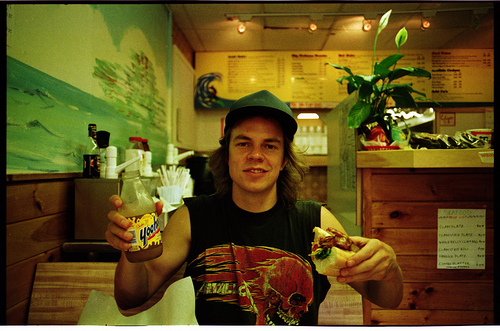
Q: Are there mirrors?
A: No, there are no mirrors.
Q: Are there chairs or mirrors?
A: No, there are no mirrors or chairs.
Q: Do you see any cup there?
A: Yes, there is a cup.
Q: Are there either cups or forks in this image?
A: Yes, there is a cup.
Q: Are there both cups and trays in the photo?
A: No, there is a cup but no trays.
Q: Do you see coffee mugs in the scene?
A: No, there are no coffee mugs.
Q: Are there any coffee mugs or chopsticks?
A: No, there are no coffee mugs or chopsticks.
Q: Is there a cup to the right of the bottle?
A: Yes, there is a cup to the right of the bottle.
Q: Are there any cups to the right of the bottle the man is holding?
A: Yes, there is a cup to the right of the bottle.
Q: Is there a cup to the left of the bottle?
A: No, the cup is to the right of the bottle.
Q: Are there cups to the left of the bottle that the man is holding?
A: No, the cup is to the right of the bottle.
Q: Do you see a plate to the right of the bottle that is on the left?
A: No, there is a cup to the right of the bottle.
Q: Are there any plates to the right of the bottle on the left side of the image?
A: No, there is a cup to the right of the bottle.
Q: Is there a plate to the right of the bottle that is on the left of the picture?
A: No, there is a cup to the right of the bottle.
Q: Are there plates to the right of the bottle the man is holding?
A: No, there is a cup to the right of the bottle.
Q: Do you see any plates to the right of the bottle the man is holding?
A: No, there is a cup to the right of the bottle.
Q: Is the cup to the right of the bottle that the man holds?
A: Yes, the cup is to the right of the bottle.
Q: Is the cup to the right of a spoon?
A: No, the cup is to the right of the bottle.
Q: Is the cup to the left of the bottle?
A: No, the cup is to the right of the bottle.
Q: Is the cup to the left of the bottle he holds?
A: No, the cup is to the right of the bottle.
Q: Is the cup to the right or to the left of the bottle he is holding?
A: The cup is to the right of the bottle.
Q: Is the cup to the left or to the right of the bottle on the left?
A: The cup is to the right of the bottle.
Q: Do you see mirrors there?
A: No, there are no mirrors.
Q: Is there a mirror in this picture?
A: No, there are no mirrors.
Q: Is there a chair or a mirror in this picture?
A: No, there are no mirrors or chairs.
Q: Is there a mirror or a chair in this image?
A: No, there are no mirrors or chairs.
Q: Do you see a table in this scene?
A: Yes, there is a table.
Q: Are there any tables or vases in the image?
A: Yes, there is a table.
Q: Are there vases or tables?
A: Yes, there is a table.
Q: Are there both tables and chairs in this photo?
A: No, there is a table but no chairs.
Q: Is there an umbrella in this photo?
A: No, there are no umbrellas.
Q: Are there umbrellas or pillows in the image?
A: No, there are no umbrellas or pillows.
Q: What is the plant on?
A: The plant is on the counter.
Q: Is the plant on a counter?
A: Yes, the plant is on a counter.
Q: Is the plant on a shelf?
A: No, the plant is on a counter.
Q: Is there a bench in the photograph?
A: Yes, there is a bench.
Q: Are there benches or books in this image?
A: Yes, there is a bench.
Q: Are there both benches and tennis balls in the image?
A: No, there is a bench but no tennis balls.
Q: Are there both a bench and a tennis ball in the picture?
A: No, there is a bench but no tennis balls.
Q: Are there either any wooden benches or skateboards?
A: Yes, there is a wood bench.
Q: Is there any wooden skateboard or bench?
A: Yes, there is a wood bench.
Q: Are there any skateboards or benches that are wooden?
A: Yes, the bench is wooden.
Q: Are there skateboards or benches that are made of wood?
A: Yes, the bench is made of wood.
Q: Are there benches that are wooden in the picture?
A: Yes, there is a wood bench.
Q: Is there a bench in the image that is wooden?
A: Yes, there is a bench that is wooden.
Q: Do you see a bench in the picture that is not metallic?
A: Yes, there is a wooden bench.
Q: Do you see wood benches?
A: Yes, there is a bench that is made of wood.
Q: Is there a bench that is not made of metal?
A: Yes, there is a bench that is made of wood.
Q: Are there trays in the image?
A: No, there are no trays.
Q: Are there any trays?
A: No, there are no trays.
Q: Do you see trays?
A: No, there are no trays.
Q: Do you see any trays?
A: No, there are no trays.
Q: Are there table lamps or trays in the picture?
A: No, there are no trays or table lamps.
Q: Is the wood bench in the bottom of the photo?
A: Yes, the bench is in the bottom of the image.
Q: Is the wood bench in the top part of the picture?
A: No, the bench is in the bottom of the image.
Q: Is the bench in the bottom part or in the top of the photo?
A: The bench is in the bottom of the image.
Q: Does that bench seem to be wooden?
A: Yes, the bench is wooden.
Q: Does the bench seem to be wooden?
A: Yes, the bench is wooden.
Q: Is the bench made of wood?
A: Yes, the bench is made of wood.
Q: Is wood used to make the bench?
A: Yes, the bench is made of wood.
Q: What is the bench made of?
A: The bench is made of wood.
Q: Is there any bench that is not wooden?
A: No, there is a bench but it is wooden.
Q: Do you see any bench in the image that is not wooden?
A: No, there is a bench but it is wooden.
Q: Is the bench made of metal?
A: No, the bench is made of wood.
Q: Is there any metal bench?
A: No, there is a bench but it is made of wood.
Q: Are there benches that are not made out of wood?
A: No, there is a bench but it is made of wood.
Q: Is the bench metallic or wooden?
A: The bench is wooden.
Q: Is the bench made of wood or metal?
A: The bench is made of wood.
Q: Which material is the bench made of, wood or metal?
A: The bench is made of wood.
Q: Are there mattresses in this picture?
A: No, there are no mattresses.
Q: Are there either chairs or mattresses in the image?
A: No, there are no mattresses or chairs.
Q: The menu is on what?
A: The menu is on the wall.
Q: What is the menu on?
A: The menu is on the wall.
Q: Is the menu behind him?
A: Yes, the menu is behind the man.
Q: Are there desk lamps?
A: No, there are no desk lamps.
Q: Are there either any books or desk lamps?
A: No, there are no desk lamps or books.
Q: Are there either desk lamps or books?
A: No, there are no desk lamps or books.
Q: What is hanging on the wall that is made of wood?
A: The paper is hanging on the wall.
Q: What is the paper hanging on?
A: The paper is hanging on the wall.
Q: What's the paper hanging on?
A: The paper is hanging on the wall.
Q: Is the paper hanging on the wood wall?
A: Yes, the paper is hanging on the wall.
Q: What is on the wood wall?
A: The paper is on the wall.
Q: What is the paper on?
A: The paper is on the wall.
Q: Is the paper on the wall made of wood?
A: Yes, the paper is on the wall.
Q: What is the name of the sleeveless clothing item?
A: The clothing item is a shirt.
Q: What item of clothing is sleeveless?
A: The clothing item is a shirt.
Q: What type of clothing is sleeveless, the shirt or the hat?
A: The shirt is sleeveless.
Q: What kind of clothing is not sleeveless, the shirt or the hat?
A: The hat is not sleeveless.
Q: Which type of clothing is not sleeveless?
A: The clothing is a hat.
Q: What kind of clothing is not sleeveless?
A: The clothing is a hat.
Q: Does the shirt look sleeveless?
A: Yes, the shirt is sleeveless.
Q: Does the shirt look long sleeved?
A: No, the shirt is sleeveless.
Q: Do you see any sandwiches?
A: Yes, there is a sandwich.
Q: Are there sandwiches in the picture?
A: Yes, there is a sandwich.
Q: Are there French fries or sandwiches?
A: Yes, there is a sandwich.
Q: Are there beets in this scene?
A: No, there are no beets.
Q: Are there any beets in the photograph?
A: No, there are no beets.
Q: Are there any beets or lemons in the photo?
A: No, there are no beets or lemons.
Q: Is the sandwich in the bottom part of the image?
A: Yes, the sandwich is in the bottom of the image.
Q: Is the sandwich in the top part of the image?
A: No, the sandwich is in the bottom of the image.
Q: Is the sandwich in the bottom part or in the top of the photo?
A: The sandwich is in the bottom of the image.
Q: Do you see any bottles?
A: Yes, there is a bottle.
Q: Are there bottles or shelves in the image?
A: Yes, there is a bottle.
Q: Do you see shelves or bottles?
A: Yes, there is a bottle.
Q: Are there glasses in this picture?
A: No, there are no glasses.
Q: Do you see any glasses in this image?
A: No, there are no glasses.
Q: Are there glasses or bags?
A: No, there are no glasses or bags.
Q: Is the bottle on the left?
A: Yes, the bottle is on the left of the image.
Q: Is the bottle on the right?
A: No, the bottle is on the left of the image.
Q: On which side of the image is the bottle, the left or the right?
A: The bottle is on the left of the image.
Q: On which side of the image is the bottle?
A: The bottle is on the left of the image.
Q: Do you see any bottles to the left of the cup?
A: Yes, there is a bottle to the left of the cup.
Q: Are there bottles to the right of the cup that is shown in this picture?
A: No, the bottle is to the left of the cup.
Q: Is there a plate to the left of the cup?
A: No, there is a bottle to the left of the cup.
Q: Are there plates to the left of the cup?
A: No, there is a bottle to the left of the cup.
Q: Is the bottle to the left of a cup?
A: Yes, the bottle is to the left of a cup.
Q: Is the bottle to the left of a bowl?
A: No, the bottle is to the left of a cup.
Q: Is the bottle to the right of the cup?
A: No, the bottle is to the left of the cup.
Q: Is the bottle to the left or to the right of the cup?
A: The bottle is to the left of the cup.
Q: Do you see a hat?
A: Yes, there is a hat.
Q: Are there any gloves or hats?
A: Yes, there is a hat.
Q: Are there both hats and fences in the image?
A: No, there is a hat but no fences.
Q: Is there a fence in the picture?
A: No, there are no fences.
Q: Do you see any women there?
A: No, there are no women.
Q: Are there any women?
A: No, there are no women.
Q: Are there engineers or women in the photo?
A: No, there are no women or engineers.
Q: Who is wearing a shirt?
A: The man is wearing a shirt.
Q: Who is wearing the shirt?
A: The man is wearing a shirt.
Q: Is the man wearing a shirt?
A: Yes, the man is wearing a shirt.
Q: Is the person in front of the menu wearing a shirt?
A: Yes, the man is wearing a shirt.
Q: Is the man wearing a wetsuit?
A: No, the man is wearing a shirt.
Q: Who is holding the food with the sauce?
A: The man is holding the sandwich.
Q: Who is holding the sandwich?
A: The man is holding the sandwich.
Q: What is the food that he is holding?
A: The food is a sandwich.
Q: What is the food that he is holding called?
A: The food is a sandwich.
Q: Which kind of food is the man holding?
A: The man is holding the sandwich.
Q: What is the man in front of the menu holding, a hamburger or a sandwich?
A: The man is holding a sandwich.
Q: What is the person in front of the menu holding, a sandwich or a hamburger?
A: The man is holding a sandwich.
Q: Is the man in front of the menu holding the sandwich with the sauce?
A: Yes, the man is holding the sandwich.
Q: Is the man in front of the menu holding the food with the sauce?
A: Yes, the man is holding the sandwich.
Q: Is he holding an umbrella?
A: No, the man is holding the sandwich.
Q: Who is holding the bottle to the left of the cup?
A: The man is holding the bottle.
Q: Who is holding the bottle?
A: The man is holding the bottle.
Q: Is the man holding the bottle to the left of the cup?
A: Yes, the man is holding the bottle.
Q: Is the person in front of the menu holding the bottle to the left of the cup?
A: Yes, the man is holding the bottle.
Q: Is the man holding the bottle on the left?
A: Yes, the man is holding the bottle.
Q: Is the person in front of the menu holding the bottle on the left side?
A: Yes, the man is holding the bottle.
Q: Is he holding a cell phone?
A: No, the man is holding the bottle.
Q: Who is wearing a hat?
A: The man is wearing a hat.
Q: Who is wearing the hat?
A: The man is wearing a hat.